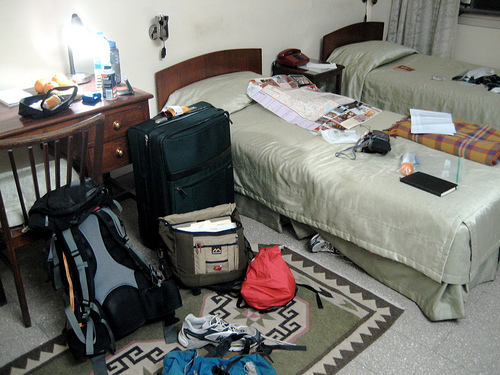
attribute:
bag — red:
[241, 246, 299, 311]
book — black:
[402, 170, 458, 197]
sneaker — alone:
[179, 314, 261, 350]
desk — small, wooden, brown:
[0, 74, 153, 306]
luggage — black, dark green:
[129, 101, 234, 251]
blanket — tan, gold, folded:
[383, 108, 499, 168]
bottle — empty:
[90, 51, 105, 89]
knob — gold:
[113, 120, 122, 131]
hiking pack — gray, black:
[24, 180, 182, 361]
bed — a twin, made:
[155, 47, 499, 325]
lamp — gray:
[67, 13, 90, 84]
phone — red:
[277, 48, 312, 67]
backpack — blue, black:
[165, 348, 275, 374]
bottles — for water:
[95, 39, 122, 93]